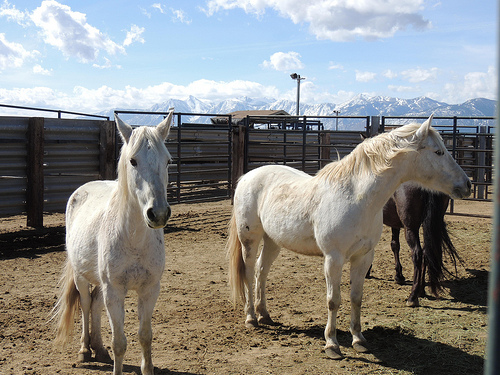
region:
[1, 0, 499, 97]
fluffy white and gray clouds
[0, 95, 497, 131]
snow topped mountains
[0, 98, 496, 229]
tall metal fence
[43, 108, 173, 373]
a white horse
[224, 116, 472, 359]
a white horse facing the right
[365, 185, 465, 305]
a dark brown horse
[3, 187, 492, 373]
a bare dirt lot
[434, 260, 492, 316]
horse's shadow on the ground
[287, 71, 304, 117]
a light on a tall pole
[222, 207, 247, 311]
long white hair on the tail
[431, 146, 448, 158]
eye on the side of the head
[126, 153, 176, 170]
two eyes on either side of the head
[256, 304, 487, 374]
shadow from the pony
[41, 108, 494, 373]
three ponies standing on the dirt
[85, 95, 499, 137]
mountains in the distance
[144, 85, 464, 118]
snow on top of the mountain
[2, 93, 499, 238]
fence around the enclosure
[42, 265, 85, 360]
tail is swishing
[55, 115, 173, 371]
the horse is facing the viewer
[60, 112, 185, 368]
the horse is standing still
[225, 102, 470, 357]
the horse is standing still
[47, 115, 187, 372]
the horse is white in color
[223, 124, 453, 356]
the horse is white in color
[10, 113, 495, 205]
a fence is behind the horses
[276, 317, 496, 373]
a shadow is on the ground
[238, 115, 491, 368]
the horse is casting a shadow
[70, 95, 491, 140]
the mountains are in the distance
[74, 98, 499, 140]
a mountain range is in the distance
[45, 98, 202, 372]
white horse in pen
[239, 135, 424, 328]
white horse in pen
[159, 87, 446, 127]
mountains in the distance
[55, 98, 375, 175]
metal corral fence for horses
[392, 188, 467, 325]
dark horse tail in pen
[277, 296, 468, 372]
shadow of horse on ground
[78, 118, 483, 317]
three horses in corral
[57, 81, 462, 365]
three horses in pen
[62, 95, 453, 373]
two white horses in corral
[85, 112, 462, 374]
two white horses in pen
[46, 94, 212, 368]
this is a horse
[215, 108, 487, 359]
this is a horse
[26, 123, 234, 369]
this horse is white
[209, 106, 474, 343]
this horse is white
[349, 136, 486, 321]
this is a horse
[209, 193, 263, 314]
the tail of a horse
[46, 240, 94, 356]
the tail of a horse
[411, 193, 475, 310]
the tail of a horse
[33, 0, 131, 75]
this is a cloud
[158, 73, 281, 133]
this is a cloud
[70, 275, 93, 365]
long leg on the horse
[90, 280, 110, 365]
long leg on the horse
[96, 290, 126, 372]
long leg on the horse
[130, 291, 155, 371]
long leg on the horse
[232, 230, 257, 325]
long leg on the horse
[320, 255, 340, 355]
long leg on the horse